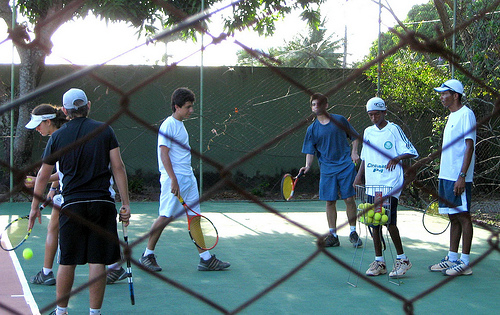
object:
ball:
[23, 248, 34, 261]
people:
[25, 79, 477, 315]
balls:
[357, 203, 388, 227]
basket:
[345, 184, 400, 288]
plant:
[363, 24, 459, 114]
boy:
[299, 92, 363, 247]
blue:
[301, 115, 358, 201]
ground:
[0, 199, 499, 315]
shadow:
[0, 232, 499, 315]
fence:
[0, 0, 499, 314]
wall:
[0, 64, 499, 174]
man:
[138, 86, 230, 272]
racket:
[173, 190, 219, 251]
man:
[429, 80, 475, 276]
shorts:
[438, 178, 472, 215]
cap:
[434, 79, 464, 95]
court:
[0, 64, 499, 315]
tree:
[0, 0, 328, 200]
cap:
[366, 97, 387, 112]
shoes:
[139, 253, 230, 271]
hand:
[171, 177, 180, 199]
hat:
[63, 88, 88, 109]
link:
[99, 80, 151, 125]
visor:
[25, 113, 57, 129]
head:
[31, 104, 65, 137]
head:
[61, 88, 91, 118]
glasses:
[440, 83, 452, 88]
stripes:
[439, 263, 449, 268]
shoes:
[429, 256, 472, 276]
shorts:
[319, 163, 358, 201]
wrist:
[457, 170, 468, 182]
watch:
[459, 172, 467, 177]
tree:
[372, 0, 499, 87]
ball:
[26, 178, 31, 182]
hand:
[25, 176, 36, 188]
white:
[156, 115, 199, 217]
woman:
[24, 103, 125, 285]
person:
[352, 97, 419, 277]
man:
[28, 88, 132, 314]